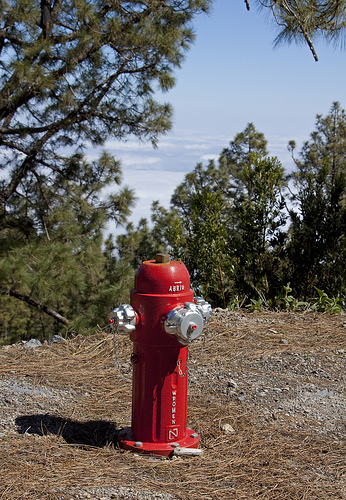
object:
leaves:
[216, 261, 226, 276]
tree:
[132, 122, 298, 309]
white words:
[170, 388, 178, 423]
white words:
[167, 281, 186, 292]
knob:
[163, 301, 204, 348]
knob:
[107, 303, 137, 333]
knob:
[187, 293, 212, 326]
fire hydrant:
[106, 250, 210, 456]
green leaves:
[21, 238, 30, 259]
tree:
[0, 1, 215, 241]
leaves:
[250, 175, 260, 182]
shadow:
[13, 410, 128, 449]